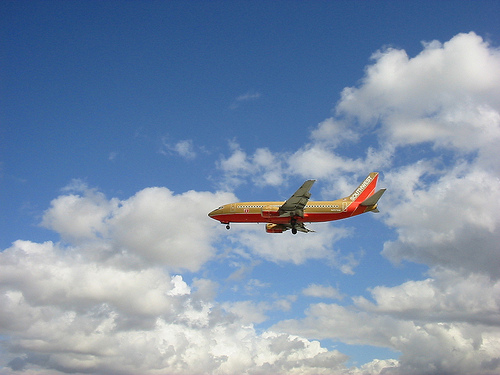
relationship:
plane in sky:
[208, 170, 389, 237] [3, 5, 500, 371]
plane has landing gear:
[208, 170, 389, 237] [283, 208, 307, 222]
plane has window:
[208, 170, 389, 237] [239, 205, 243, 210]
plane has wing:
[208, 170, 389, 237] [279, 173, 317, 224]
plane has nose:
[208, 170, 389, 237] [208, 203, 230, 225]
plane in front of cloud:
[208, 170, 389, 237] [309, 32, 499, 159]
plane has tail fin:
[208, 170, 389, 237] [344, 172, 386, 213]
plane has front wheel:
[208, 170, 389, 237] [223, 221, 232, 234]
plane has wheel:
[208, 170, 389, 237] [288, 213, 300, 226]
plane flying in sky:
[208, 170, 389, 237] [3, 5, 500, 371]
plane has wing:
[208, 170, 389, 237] [279, 215, 316, 239]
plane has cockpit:
[208, 170, 389, 237] [223, 202, 241, 216]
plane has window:
[208, 170, 389, 237] [254, 204, 259, 211]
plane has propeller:
[208, 170, 389, 237] [277, 194, 312, 200]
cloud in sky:
[113, 184, 231, 265] [3, 5, 500, 371]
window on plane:
[239, 205, 243, 210] [208, 170, 389, 237]